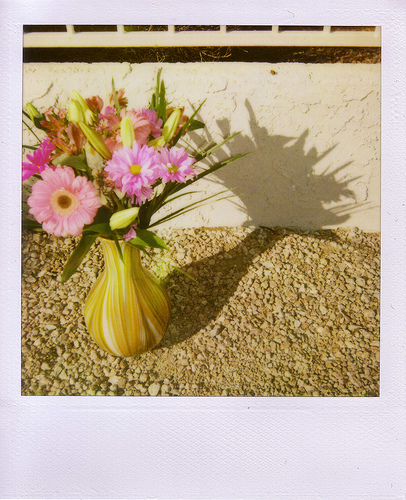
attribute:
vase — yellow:
[73, 235, 182, 357]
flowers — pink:
[32, 96, 215, 234]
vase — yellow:
[75, 216, 203, 358]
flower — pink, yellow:
[38, 91, 219, 263]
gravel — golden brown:
[22, 224, 380, 395]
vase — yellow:
[76, 207, 174, 363]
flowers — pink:
[30, 160, 180, 240]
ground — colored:
[21, 220, 379, 403]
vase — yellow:
[45, 214, 190, 360]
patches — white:
[83, 250, 170, 356]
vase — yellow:
[80, 227, 172, 356]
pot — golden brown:
[82, 229, 170, 357]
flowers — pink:
[57, 117, 189, 217]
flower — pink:
[26, 162, 103, 240]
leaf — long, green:
[59, 222, 106, 281]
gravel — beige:
[262, 286, 353, 371]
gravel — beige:
[200, 257, 324, 369]